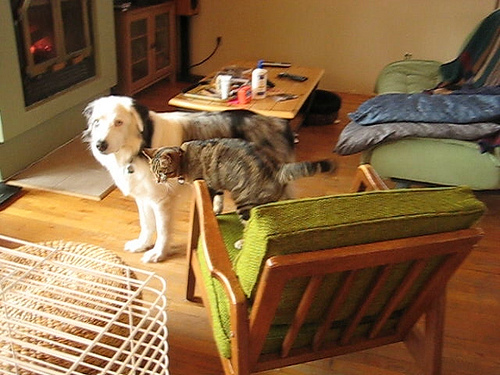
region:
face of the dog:
[56, 77, 136, 167]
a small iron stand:
[51, 230, 160, 358]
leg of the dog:
[128, 222, 195, 280]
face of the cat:
[132, 148, 199, 195]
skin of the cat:
[208, 142, 238, 166]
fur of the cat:
[197, 155, 232, 172]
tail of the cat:
[286, 150, 348, 189]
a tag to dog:
[131, 140, 160, 156]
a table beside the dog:
[187, 50, 379, 145]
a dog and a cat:
[63, 82, 300, 244]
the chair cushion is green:
[230, 198, 325, 278]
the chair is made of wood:
[257, 255, 342, 335]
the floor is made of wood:
[40, 194, 138, 266]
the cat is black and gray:
[161, 143, 376, 259]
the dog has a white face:
[88, 109, 143, 166]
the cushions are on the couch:
[350, 73, 499, 223]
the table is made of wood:
[178, 82, 489, 221]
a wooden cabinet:
[115, 12, 173, 80]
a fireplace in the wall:
[11, 5, 101, 82]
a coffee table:
[178, 51, 315, 113]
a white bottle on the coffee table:
[250, 63, 269, 95]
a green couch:
[366, 30, 498, 197]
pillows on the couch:
[348, 89, 495, 139]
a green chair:
[191, 179, 448, 372]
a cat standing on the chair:
[148, 132, 297, 211]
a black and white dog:
[82, 85, 277, 252]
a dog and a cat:
[71, 92, 302, 215]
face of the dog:
[66, 63, 148, 179]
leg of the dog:
[118, 194, 190, 276]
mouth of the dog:
[86, 120, 118, 167]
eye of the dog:
[106, 113, 130, 136]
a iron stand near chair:
[36, 252, 203, 370]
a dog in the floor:
[87, 88, 303, 250]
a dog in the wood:
[70, 98, 332, 244]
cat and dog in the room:
[76, 103, 295, 196]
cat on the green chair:
[148, 148, 413, 287]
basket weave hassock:
[0, 253, 148, 350]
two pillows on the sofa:
[336, 89, 493, 161]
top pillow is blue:
[350, 89, 491, 129]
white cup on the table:
[208, 72, 238, 108]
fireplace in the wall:
[9, 5, 94, 80]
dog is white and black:
[90, 87, 160, 252]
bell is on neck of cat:
[176, 156, 186, 198]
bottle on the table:
[248, 59, 273, 110]